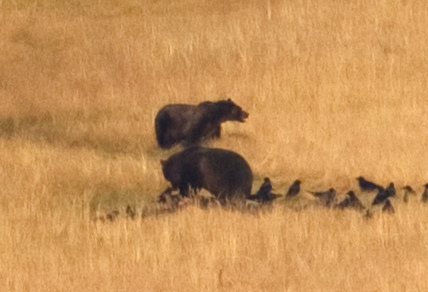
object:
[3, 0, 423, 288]
field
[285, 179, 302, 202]
bird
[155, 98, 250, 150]
bear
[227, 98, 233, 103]
ear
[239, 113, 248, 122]
mouth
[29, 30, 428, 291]
grass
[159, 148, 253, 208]
bears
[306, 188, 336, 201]
duck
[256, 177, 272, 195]
birds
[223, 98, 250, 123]
head